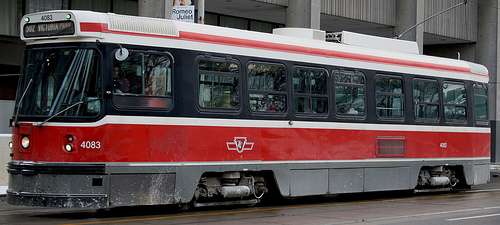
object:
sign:
[15, 19, 82, 39]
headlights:
[18, 132, 40, 150]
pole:
[399, 2, 469, 35]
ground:
[406, 167, 437, 195]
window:
[237, 58, 290, 116]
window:
[194, 55, 244, 112]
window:
[294, 69, 329, 114]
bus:
[6, 10, 492, 214]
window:
[101, 41, 176, 111]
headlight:
[57, 132, 77, 154]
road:
[7, 180, 497, 224]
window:
[438, 82, 473, 120]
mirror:
[112, 44, 136, 64]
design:
[225, 135, 255, 153]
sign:
[160, 0, 199, 23]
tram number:
[79, 139, 110, 149]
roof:
[74, 5, 490, 79]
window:
[363, 70, 409, 121]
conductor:
[105, 64, 140, 111]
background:
[14, 128, 494, 163]